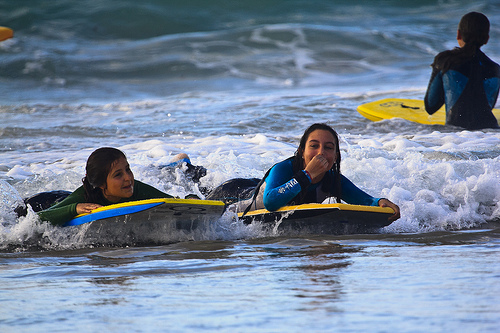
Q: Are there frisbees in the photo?
A: No, there are no frisbees.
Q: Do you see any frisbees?
A: No, there are no frisbees.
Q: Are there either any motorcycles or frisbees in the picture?
A: No, there are no frisbees or motorcycles.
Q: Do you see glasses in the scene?
A: No, there are no glasses.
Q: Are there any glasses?
A: No, there are no glasses.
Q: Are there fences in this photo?
A: No, there are no fences.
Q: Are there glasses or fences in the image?
A: No, there are no fences or glasses.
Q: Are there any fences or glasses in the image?
A: No, there are no fences or glasses.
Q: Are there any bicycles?
A: No, there are no bicycles.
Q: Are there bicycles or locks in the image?
A: No, there are no bicycles or locks.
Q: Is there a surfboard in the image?
A: Yes, there is a surfboard.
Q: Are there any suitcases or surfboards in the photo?
A: Yes, there is a surfboard.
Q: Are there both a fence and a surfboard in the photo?
A: No, there is a surfboard but no fences.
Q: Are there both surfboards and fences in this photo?
A: No, there is a surfboard but no fences.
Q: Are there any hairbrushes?
A: No, there are no hairbrushes.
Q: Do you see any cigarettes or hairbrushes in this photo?
A: No, there are no hairbrushes or cigarettes.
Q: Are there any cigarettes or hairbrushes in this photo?
A: No, there are no hairbrushes or cigarettes.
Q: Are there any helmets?
A: No, there are no helmets.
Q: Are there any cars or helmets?
A: No, there are no helmets or cars.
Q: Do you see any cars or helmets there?
A: No, there are no helmets or cars.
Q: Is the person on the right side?
A: Yes, the person is on the right of the image.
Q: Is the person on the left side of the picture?
A: No, the person is on the right of the image.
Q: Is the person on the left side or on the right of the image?
A: The person is on the right of the image.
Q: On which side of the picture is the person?
A: The person is on the right of the image.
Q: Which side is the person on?
A: The person is on the right of the image.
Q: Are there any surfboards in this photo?
A: Yes, there is a surfboard.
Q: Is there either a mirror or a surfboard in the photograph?
A: Yes, there is a surfboard.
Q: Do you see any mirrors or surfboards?
A: Yes, there is a surfboard.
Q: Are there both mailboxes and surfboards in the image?
A: No, there is a surfboard but no mailboxes.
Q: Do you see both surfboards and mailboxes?
A: No, there is a surfboard but no mailboxes.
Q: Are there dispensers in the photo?
A: No, there are no dispensers.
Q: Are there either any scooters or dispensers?
A: No, there are no dispensers or scooters.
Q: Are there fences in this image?
A: No, there are no fences.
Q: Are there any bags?
A: No, there are no bags.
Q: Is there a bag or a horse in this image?
A: No, there are no bags or horses.